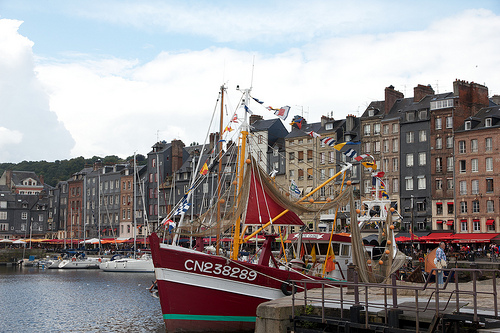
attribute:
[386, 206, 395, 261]
balls — orange 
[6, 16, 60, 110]
cloud — large, fluffy, white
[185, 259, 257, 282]
writing — white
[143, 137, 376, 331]
ship — red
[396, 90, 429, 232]
building — grey 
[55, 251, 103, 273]
boat — docked  , white  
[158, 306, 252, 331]
stripe — green 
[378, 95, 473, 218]
building — ball  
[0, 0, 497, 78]
sky — clear, blue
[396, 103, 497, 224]
building — narrow 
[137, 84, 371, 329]
boat — large, red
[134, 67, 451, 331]
boat — red , white 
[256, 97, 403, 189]
pennants — colorful 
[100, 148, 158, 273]
white boat — white 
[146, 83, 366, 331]
sailboat — large , red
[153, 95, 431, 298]
mast — yellow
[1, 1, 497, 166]
sky — cloudy , blue  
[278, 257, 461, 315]
boat dock — concrete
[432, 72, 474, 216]
building — tall , red, brick 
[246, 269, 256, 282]
number — white 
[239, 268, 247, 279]
number — white 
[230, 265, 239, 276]
number — white 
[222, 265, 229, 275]
number — white 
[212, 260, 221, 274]
number — white 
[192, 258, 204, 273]
letter — white 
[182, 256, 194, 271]
letter — white 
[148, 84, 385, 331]
boat — white 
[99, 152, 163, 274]
boat — white 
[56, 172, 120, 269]
boat — white 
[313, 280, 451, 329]
dock — wooden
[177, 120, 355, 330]
boat — red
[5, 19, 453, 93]
clouds — big 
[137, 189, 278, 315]
boat — red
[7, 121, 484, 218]
buildings — tall 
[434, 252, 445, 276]
outfit — blue 